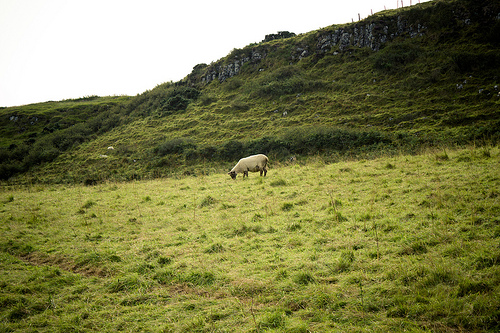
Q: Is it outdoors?
A: Yes, it is outdoors.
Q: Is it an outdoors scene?
A: Yes, it is outdoors.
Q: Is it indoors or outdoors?
A: It is outdoors.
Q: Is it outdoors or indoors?
A: It is outdoors.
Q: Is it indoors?
A: No, it is outdoors.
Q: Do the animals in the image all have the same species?
A: Yes, all the animals are sheep.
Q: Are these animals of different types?
A: No, all the animals are sheep.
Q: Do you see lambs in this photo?
A: Yes, there is a lamb.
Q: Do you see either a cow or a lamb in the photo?
A: Yes, there is a lamb.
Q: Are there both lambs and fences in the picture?
A: No, there is a lamb but no fences.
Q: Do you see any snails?
A: No, there are no snails.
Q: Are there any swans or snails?
A: No, there are no snails or swans.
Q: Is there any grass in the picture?
A: Yes, there is grass.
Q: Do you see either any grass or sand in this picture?
A: Yes, there is grass.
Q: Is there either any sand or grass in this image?
A: Yes, there is grass.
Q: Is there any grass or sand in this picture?
A: Yes, there is grass.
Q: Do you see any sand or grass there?
A: Yes, there is grass.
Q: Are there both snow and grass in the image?
A: No, there is grass but no snow.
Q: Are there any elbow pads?
A: No, there are no elbow pads.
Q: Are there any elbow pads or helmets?
A: No, there are no elbow pads or helmets.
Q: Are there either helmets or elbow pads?
A: No, there are no elbow pads or helmets.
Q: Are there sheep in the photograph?
A: Yes, there is a sheep.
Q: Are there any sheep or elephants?
A: Yes, there is a sheep.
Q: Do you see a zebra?
A: No, there are no zebras.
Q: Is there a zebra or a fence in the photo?
A: No, there are no zebras or fences.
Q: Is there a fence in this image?
A: No, there are no fences.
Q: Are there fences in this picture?
A: No, there are no fences.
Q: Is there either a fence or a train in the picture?
A: No, there are no fences or trains.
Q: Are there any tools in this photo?
A: No, there are no tools.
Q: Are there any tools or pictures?
A: No, there are no tools or pictures.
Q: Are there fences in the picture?
A: No, there are no fences.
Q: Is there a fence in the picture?
A: No, there are no fences.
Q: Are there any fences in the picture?
A: No, there are no fences.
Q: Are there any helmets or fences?
A: No, there are no fences or helmets.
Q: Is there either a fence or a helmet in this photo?
A: No, there are no fences or helmets.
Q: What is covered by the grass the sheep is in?
A: The field is covered by the grass.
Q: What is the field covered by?
A: The field is covered by the grass.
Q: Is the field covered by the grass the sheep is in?
A: Yes, the field is covered by the grass.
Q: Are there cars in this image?
A: No, there are no cars.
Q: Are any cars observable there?
A: No, there are no cars.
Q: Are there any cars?
A: No, there are no cars.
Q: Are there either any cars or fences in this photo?
A: No, there are no cars or fences.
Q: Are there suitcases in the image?
A: No, there are no suitcases.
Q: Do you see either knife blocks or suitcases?
A: No, there are no suitcases or knife blocks.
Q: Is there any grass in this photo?
A: Yes, there is grass.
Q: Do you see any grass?
A: Yes, there is grass.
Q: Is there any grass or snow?
A: Yes, there is grass.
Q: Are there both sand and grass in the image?
A: No, there is grass but no sand.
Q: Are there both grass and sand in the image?
A: No, there is grass but no sand.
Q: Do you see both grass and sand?
A: No, there is grass but no sand.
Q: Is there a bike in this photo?
A: No, there are no bikes.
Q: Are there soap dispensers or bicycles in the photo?
A: No, there are no bicycles or soap dispensers.